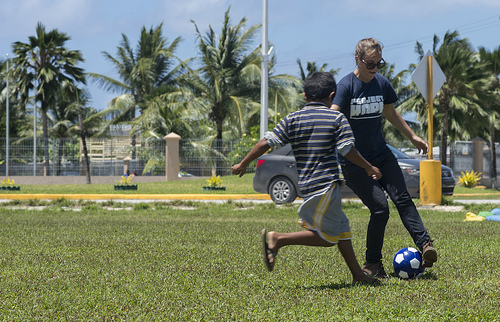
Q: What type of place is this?
A: It is a field.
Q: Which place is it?
A: It is a field.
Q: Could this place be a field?
A: Yes, it is a field.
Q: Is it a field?
A: Yes, it is a field.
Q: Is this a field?
A: Yes, it is a field.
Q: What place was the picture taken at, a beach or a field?
A: It was taken at a field.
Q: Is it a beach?
A: No, it is a field.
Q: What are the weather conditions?
A: It is clear.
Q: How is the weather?
A: It is clear.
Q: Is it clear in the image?
A: Yes, it is clear.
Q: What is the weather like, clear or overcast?
A: It is clear.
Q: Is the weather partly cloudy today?
A: No, it is clear.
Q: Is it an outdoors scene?
A: Yes, it is outdoors.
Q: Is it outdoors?
A: Yes, it is outdoors.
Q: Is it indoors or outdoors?
A: It is outdoors.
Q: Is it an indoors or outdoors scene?
A: It is outdoors.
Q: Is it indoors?
A: No, it is outdoors.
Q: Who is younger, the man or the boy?
A: The boy is younger than the man.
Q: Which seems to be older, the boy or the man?
A: The man is older than the boy.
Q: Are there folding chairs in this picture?
A: No, there are no folding chairs.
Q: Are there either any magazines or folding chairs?
A: No, there are no folding chairs or magazines.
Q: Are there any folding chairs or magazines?
A: No, there are no folding chairs or magazines.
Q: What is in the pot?
A: The flowers are in the pot.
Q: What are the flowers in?
A: The flowers are in the pot.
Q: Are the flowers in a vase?
A: No, the flowers are in a pot.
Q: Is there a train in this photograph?
A: No, there are no trains.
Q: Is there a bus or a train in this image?
A: No, there are no trains or buses.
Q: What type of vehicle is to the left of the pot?
A: The vehicle is a car.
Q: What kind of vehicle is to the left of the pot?
A: The vehicle is a car.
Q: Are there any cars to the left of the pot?
A: Yes, there is a car to the left of the pot.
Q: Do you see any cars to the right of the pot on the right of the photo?
A: No, the car is to the left of the pot.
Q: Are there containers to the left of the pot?
A: No, there is a car to the left of the pot.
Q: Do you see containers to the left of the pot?
A: No, there is a car to the left of the pot.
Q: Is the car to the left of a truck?
A: No, the car is to the left of a pot.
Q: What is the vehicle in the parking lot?
A: The vehicle is a car.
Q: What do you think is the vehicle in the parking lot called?
A: The vehicle is a car.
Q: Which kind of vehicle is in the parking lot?
A: The vehicle is a car.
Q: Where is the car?
A: The car is in the parking lot.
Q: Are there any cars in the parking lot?
A: Yes, there is a car in the parking lot.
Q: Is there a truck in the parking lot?
A: No, there is a car in the parking lot.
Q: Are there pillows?
A: No, there are no pillows.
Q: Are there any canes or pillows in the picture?
A: No, there are no pillows or canes.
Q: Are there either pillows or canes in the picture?
A: No, there are no pillows or canes.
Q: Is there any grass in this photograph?
A: Yes, there is grass.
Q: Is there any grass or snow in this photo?
A: Yes, there is grass.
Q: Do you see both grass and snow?
A: No, there is grass but no snow.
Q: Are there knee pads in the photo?
A: No, there are no knee pads.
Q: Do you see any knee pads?
A: No, there are no knee pads.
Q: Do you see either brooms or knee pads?
A: No, there are no knee pads or brooms.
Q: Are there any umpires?
A: No, there are no umpires.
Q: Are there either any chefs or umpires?
A: No, there are no umpires or chefs.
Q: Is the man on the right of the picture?
A: Yes, the man is on the right of the image.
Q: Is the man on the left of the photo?
A: No, the man is on the right of the image.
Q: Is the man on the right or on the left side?
A: The man is on the right of the image.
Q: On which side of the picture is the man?
A: The man is on the right of the image.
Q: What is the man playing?
A: The man is playing soccer.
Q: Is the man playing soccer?
A: Yes, the man is playing soccer.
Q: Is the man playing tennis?
A: No, the man is playing soccer.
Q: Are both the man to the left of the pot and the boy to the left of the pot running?
A: Yes, both the man and the boy are running.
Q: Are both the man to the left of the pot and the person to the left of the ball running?
A: Yes, both the man and the boy are running.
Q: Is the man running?
A: Yes, the man is running.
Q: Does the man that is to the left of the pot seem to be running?
A: Yes, the man is running.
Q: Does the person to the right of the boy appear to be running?
A: Yes, the man is running.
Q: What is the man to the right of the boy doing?
A: The man is running.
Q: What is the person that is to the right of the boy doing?
A: The man is running.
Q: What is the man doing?
A: The man is running.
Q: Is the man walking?
A: No, the man is running.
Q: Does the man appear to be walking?
A: No, the man is running.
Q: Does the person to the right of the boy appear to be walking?
A: No, the man is running.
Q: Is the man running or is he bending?
A: The man is running.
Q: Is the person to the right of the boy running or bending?
A: The man is running.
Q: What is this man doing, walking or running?
A: The man is running.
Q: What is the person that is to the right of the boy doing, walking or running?
A: The man is running.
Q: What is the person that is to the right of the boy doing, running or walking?
A: The man is running.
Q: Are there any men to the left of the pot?
A: Yes, there is a man to the left of the pot.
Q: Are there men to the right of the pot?
A: No, the man is to the left of the pot.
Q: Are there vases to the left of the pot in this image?
A: No, there is a man to the left of the pot.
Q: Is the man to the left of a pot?
A: Yes, the man is to the left of a pot.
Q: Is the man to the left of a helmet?
A: No, the man is to the left of a pot.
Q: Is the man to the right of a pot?
A: No, the man is to the left of a pot.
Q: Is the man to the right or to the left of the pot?
A: The man is to the left of the pot.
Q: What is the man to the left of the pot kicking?
A: The man is kicking the ball.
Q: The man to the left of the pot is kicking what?
A: The man is kicking the ball.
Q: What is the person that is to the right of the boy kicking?
A: The man is kicking the ball.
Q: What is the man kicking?
A: The man is kicking the ball.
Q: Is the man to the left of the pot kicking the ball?
A: Yes, the man is kicking the ball.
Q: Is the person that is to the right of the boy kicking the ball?
A: Yes, the man is kicking the ball.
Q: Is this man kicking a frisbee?
A: No, the man is kicking the ball.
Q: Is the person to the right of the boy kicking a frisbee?
A: No, the man is kicking the ball.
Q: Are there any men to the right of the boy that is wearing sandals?
A: Yes, there is a man to the right of the boy.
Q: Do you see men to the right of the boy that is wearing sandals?
A: Yes, there is a man to the right of the boy.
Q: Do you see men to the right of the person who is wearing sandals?
A: Yes, there is a man to the right of the boy.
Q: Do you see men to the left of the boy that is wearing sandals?
A: No, the man is to the right of the boy.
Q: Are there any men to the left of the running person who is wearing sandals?
A: No, the man is to the right of the boy.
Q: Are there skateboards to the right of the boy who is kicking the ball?
A: No, there is a man to the right of the boy.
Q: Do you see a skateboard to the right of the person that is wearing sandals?
A: No, there is a man to the right of the boy.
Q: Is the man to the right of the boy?
A: Yes, the man is to the right of the boy.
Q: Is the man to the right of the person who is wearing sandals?
A: Yes, the man is to the right of the boy.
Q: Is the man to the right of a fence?
A: No, the man is to the right of the boy.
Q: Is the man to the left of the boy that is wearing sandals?
A: No, the man is to the right of the boy.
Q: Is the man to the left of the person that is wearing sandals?
A: No, the man is to the right of the boy.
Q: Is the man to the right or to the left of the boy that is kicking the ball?
A: The man is to the right of the boy.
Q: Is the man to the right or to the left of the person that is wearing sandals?
A: The man is to the right of the boy.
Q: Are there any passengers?
A: No, there are no passengers.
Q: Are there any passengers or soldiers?
A: No, there are no passengers or soldiers.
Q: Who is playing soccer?
A: The boy is playing soccer.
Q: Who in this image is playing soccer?
A: The boy is playing soccer.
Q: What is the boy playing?
A: The boy is playing soccer.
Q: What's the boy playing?
A: The boy is playing soccer.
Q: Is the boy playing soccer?
A: Yes, the boy is playing soccer.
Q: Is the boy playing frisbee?
A: No, the boy is playing soccer.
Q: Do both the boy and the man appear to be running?
A: Yes, both the boy and the man are running.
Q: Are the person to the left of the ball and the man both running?
A: Yes, both the boy and the man are running.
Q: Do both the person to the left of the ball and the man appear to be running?
A: Yes, both the boy and the man are running.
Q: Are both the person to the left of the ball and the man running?
A: Yes, both the boy and the man are running.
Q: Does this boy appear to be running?
A: Yes, the boy is running.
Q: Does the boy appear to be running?
A: Yes, the boy is running.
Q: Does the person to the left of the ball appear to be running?
A: Yes, the boy is running.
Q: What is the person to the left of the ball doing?
A: The boy is running.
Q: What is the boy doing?
A: The boy is running.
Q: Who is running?
A: The boy is running.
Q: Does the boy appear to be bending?
A: No, the boy is running.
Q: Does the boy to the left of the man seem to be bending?
A: No, the boy is running.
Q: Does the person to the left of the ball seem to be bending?
A: No, the boy is running.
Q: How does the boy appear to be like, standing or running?
A: The boy is running.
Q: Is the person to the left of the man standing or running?
A: The boy is running.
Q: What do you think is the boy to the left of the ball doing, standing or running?
A: The boy is running.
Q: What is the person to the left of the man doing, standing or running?
A: The boy is running.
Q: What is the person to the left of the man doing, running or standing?
A: The boy is running.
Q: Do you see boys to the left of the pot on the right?
A: Yes, there is a boy to the left of the pot.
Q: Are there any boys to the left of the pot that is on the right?
A: Yes, there is a boy to the left of the pot.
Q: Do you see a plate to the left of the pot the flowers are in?
A: No, there is a boy to the left of the pot.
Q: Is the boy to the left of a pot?
A: Yes, the boy is to the left of a pot.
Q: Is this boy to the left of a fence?
A: No, the boy is to the left of a pot.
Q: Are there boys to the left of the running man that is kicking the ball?
A: Yes, there is a boy to the left of the man.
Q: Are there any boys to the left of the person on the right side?
A: Yes, there is a boy to the left of the man.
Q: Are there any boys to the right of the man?
A: No, the boy is to the left of the man.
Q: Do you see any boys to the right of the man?
A: No, the boy is to the left of the man.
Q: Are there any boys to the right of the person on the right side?
A: No, the boy is to the left of the man.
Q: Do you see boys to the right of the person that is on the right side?
A: No, the boy is to the left of the man.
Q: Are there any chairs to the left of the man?
A: No, there is a boy to the left of the man.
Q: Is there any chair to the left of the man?
A: No, there is a boy to the left of the man.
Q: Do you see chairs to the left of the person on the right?
A: No, there is a boy to the left of the man.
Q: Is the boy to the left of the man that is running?
A: Yes, the boy is to the left of the man.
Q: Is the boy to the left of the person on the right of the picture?
A: Yes, the boy is to the left of the man.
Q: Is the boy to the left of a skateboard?
A: No, the boy is to the left of the man.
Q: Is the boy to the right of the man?
A: No, the boy is to the left of the man.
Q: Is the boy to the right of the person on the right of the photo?
A: No, the boy is to the left of the man.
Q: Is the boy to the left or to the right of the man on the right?
A: The boy is to the left of the man.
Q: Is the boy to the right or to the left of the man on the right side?
A: The boy is to the left of the man.